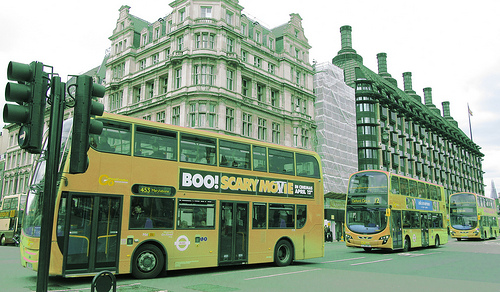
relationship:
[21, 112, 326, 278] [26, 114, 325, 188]
bus has level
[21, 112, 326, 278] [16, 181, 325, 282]
bus has level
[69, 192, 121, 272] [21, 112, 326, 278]
doors to bus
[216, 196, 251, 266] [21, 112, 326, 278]
doors to bus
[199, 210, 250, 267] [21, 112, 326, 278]
doors on bus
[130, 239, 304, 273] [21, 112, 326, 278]
tires on bus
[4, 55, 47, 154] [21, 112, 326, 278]
traffic signals in front of bus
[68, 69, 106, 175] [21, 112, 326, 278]
traffic signals in front of bus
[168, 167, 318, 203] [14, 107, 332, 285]
advertisement on bus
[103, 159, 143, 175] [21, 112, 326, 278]
yellow part of bus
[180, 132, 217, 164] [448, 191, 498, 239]
window of bus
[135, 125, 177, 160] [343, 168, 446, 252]
window of bus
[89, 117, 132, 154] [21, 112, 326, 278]
window of bus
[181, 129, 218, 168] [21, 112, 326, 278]
window on bus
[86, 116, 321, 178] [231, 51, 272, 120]
windows on upper level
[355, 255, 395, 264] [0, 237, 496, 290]
line in street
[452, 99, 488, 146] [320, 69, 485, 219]
flag on building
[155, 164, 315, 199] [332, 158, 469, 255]
advertisement on bus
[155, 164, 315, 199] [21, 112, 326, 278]
advertisement on bus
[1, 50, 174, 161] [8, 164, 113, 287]
traffic signals on black pole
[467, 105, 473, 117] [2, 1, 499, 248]
flag on top of building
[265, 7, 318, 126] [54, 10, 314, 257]
dormer of building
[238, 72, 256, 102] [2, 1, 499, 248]
window in building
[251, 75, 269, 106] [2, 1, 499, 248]
window in building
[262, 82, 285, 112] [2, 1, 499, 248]
window in building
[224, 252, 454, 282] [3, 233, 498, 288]
lines on street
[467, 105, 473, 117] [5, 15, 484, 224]
flag on top of building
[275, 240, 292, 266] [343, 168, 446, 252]
back wheel of bus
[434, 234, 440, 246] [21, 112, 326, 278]
back wheel of bus